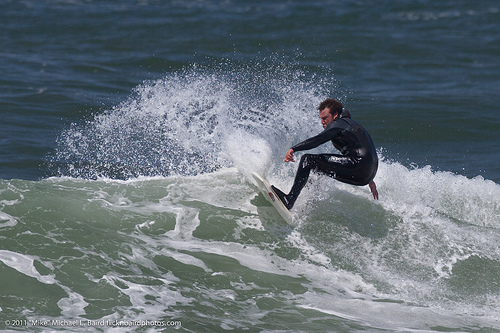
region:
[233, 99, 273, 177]
part of a splash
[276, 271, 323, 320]
part of a water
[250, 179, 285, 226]
edge of a board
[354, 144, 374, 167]
part of a costume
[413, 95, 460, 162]
part of a water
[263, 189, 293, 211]
edge of a board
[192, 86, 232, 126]
part of a splash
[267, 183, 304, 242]
part of a board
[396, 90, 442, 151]
part of a water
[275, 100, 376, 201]
crouching man over water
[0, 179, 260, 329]
white seafoam on wave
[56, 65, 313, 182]
white water drops flying in the air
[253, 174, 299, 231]
white surfboard on wave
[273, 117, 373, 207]
black wetsuit on man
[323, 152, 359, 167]
light reflection on wetsuit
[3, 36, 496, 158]
ripples on water surface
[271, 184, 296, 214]
wetsuit bootie on foot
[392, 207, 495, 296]
top of crashing wave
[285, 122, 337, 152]
extended arm of surfer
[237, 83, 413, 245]
man surfing a wave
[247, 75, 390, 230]
man wearing a black wetsuit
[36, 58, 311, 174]
drops of water coming off the wave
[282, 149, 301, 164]
hand sticking out of the wetsuit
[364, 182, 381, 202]
hand behind the body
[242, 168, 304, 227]
white surfboard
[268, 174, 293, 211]
feet firmly planted on the board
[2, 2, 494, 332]
body of water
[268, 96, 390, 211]
man that is hunched over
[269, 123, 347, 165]
arm extended in front of the body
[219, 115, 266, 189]
part of a splash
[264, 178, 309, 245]
edge of a board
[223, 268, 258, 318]
part of a water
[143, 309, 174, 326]
part of a graphic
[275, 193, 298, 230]
part of a board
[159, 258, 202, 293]
part of a water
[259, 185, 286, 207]
part of a board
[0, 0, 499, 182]
The water is blue.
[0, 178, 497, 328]
The water is green.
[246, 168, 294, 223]
The surfboard is white.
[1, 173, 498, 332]
The wave is small.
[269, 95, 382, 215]
The person is wearing a wetsuit.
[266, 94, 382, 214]
The wetsuit is black.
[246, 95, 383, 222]
The person is on a surfboard.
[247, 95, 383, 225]
The person is riding a wave.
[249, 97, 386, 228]
The person is wet.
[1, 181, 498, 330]
Foam is in the water.